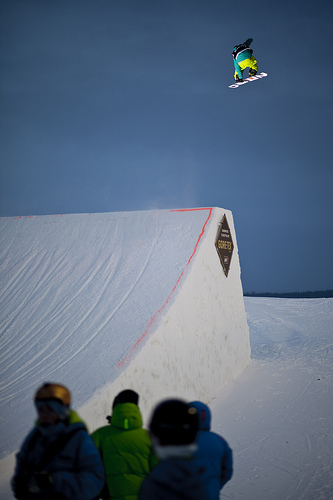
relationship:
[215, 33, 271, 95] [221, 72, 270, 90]
person on a snowboard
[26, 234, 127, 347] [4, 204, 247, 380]
tracks on pike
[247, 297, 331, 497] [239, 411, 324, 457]
snow on ground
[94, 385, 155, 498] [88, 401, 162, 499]
person wearing coat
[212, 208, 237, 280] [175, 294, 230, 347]
sign on snow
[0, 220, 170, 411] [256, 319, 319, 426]
tracks in snow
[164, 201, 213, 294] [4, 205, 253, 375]
marking on ramp